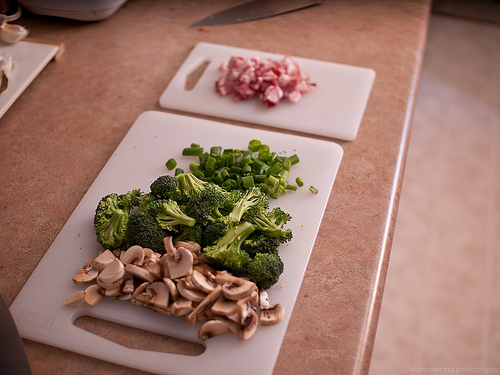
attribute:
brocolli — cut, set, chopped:
[119, 163, 246, 240]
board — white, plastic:
[156, 129, 185, 152]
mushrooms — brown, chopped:
[144, 266, 214, 325]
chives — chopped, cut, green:
[211, 148, 284, 180]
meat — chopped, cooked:
[229, 64, 300, 102]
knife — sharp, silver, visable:
[220, 4, 277, 27]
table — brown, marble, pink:
[371, 26, 395, 59]